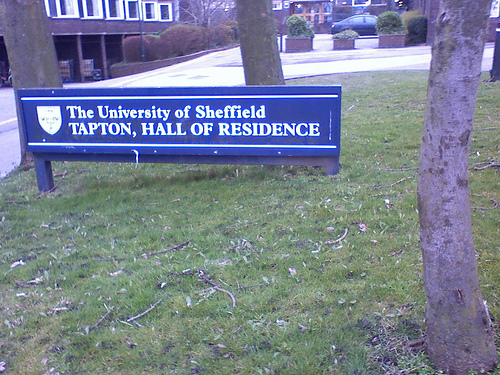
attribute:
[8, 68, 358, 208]
sign — dark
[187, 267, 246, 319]
stick — brown, small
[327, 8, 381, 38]
car — black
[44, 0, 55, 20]
window — white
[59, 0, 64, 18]
window — white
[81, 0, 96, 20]
window — white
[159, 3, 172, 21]
window — white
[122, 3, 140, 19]
window — white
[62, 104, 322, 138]
text — white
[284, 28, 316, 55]
pot — square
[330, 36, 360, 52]
pot — square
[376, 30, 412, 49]
pot — square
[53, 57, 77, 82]
object — brown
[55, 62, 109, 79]
fence — black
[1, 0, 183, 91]
building — dark brick brown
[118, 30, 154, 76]
bush — brown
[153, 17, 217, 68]
bush — brown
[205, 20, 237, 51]
bush — brown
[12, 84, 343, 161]
sign — blue, long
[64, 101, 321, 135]
writing — white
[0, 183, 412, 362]
branches — broken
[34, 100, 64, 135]
logo — white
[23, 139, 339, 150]
stripe — white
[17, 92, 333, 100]
stripe — white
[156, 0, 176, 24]
window — white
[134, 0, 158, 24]
window — white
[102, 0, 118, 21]
window — white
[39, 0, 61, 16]
window — white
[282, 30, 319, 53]
planter — red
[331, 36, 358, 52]
planter — red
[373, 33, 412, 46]
planter — red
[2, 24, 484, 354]
tree trunks — three